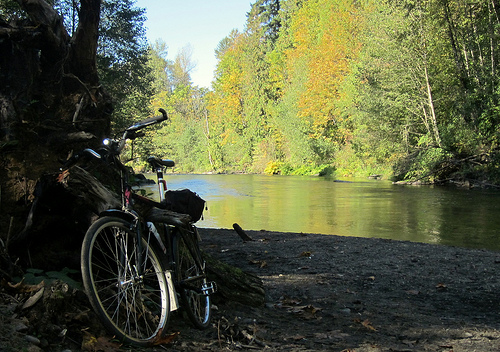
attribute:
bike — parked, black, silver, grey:
[64, 106, 222, 344]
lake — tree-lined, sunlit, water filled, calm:
[136, 168, 499, 254]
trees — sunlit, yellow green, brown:
[0, 0, 500, 190]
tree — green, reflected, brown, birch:
[341, 0, 456, 168]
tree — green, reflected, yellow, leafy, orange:
[299, 1, 374, 180]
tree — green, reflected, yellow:
[264, 3, 302, 97]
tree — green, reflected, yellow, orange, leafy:
[209, 27, 264, 177]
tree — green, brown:
[445, 1, 499, 138]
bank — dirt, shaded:
[84, 224, 500, 351]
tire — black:
[172, 227, 213, 330]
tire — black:
[80, 213, 173, 348]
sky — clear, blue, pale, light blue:
[54, 1, 281, 96]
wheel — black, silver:
[75, 211, 176, 347]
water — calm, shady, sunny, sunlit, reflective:
[128, 171, 500, 254]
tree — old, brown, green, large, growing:
[3, 1, 116, 135]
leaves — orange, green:
[300, 44, 350, 130]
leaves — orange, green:
[206, 91, 239, 129]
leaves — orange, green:
[220, 44, 243, 90]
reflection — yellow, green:
[208, 174, 409, 237]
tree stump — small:
[231, 221, 255, 245]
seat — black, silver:
[146, 154, 178, 175]